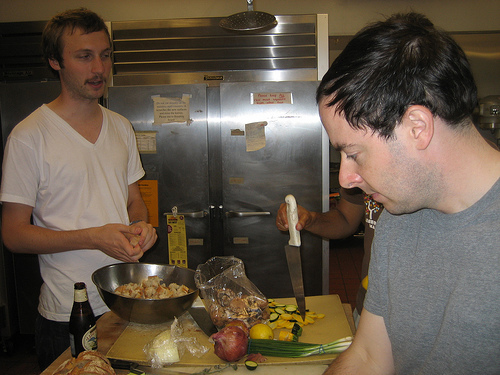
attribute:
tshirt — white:
[1, 102, 146, 321]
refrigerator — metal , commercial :
[105, 12, 327, 297]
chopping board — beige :
[101, 293, 352, 373]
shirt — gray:
[350, 205, 491, 362]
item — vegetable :
[122, 264, 276, 374]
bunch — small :
[248, 325, 356, 360]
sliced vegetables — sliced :
[252, 300, 337, 352]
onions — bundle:
[216, 316, 261, 373]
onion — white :
[145, 322, 187, 363]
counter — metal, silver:
[85, 270, 332, 355]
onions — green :
[249, 331, 354, 361]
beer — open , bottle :
[72, 281, 111, 357]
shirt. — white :
[11, 101, 140, 311]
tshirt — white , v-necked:
[14, 95, 157, 214]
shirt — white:
[2, 96, 152, 325]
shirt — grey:
[355, 181, 498, 371]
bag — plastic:
[190, 246, 270, 322]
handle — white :
[281, 190, 304, 248]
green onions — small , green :
[235, 330, 374, 360]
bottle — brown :
[67, 273, 104, 356]